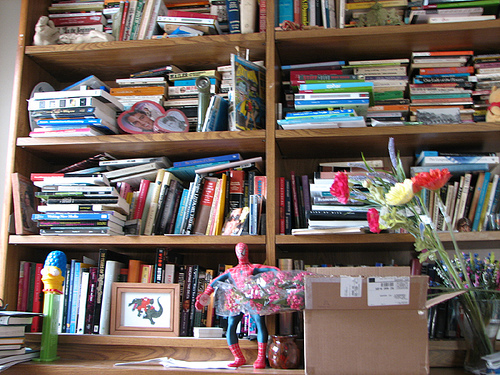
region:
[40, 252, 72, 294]
the head of a cartoon character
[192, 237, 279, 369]
spider man standing up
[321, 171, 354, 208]
a pink flower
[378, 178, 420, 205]
a yellow flower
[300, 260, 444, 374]
a brown cardboard box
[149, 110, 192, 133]
heart shaped picture frame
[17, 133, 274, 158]
a piece of a brown shelf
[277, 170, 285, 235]
a red book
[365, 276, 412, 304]
a white packaging sticker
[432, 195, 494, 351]
a green flower stem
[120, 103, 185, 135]
two heart shaped images of elvis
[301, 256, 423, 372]
an open carboard box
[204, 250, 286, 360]
a plastic spiderman figure on a shelf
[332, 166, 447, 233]
a group of pink and yellow flowers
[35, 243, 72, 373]
a Marge Simpson pez dispenser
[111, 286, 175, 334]
a framed image of a crocodile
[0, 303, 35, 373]
a pile of books on a table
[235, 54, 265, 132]
a batman and robin comic book sticking out of a shelf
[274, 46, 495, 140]
a shelf of books stacked on their side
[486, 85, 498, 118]
the side of a winnie the pooh figurine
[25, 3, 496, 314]
A bookshelf full of books.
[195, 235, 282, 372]
A spiderman figurine.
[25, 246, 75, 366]
A Marge Simpson pez dispenser.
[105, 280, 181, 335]
A small framed picture of an alligator.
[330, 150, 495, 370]
Flowers in a vase.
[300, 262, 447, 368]
A small cardboard box.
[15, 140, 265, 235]
The books on the shelf are in disarray.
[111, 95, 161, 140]
A heart-shaped picture of Elvis.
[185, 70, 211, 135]
A flashlight.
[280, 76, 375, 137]
A stack of books.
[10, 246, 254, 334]
a shelf of stacked books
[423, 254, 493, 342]
a shelf of stacked books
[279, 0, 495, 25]
a shelf of stacked books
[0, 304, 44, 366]
a stack of books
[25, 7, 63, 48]
a grey rabbit figurine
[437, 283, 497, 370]
a clear glass vase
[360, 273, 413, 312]
a white mailing sticker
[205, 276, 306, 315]
red bagged flower stems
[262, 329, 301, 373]
a small red brown vase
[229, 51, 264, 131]
a Batman comic book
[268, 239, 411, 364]
the box is brown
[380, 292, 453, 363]
the box is brown